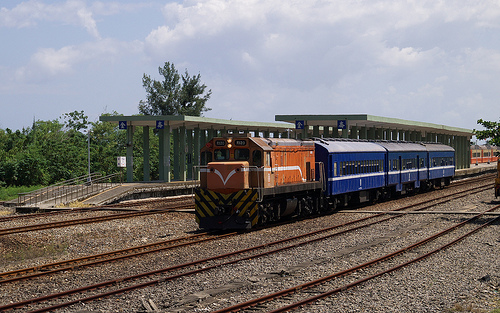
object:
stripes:
[195, 187, 259, 229]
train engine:
[187, 125, 459, 240]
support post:
[159, 123, 171, 182]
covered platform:
[99, 113, 481, 184]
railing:
[17, 171, 124, 208]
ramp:
[20, 172, 107, 206]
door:
[395, 155, 402, 191]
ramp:
[36, 185, 145, 207]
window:
[334, 163, 339, 176]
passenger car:
[192, 134, 458, 232]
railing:
[241, 162, 264, 203]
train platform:
[98, 113, 478, 185]